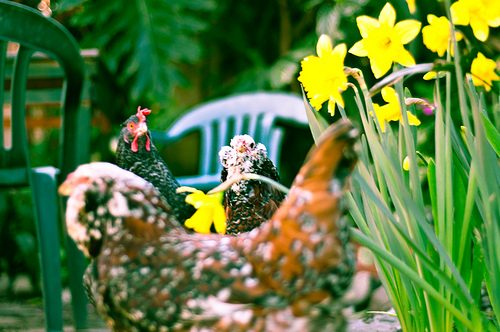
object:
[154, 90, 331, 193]
chair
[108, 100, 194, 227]
chicken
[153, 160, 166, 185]
feathers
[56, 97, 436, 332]
chicken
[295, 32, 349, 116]
bloom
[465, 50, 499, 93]
bloom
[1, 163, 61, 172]
table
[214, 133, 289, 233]
chicken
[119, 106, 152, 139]
head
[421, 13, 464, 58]
flower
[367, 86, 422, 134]
flower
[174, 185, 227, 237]
flower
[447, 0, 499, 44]
bloom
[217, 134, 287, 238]
gobbler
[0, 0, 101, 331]
chair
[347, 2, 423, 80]
buttercup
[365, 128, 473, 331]
green stems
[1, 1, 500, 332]
garden